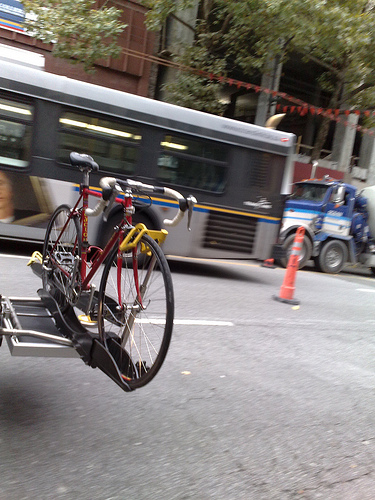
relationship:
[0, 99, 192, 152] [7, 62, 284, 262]
yellow light inside of bus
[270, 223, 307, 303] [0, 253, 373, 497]
cone on pavement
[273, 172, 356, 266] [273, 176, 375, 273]
cab on cab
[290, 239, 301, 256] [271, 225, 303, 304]
white part of cone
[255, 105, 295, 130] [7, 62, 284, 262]
exhaust of bus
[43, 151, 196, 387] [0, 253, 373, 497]
bicycle above pavement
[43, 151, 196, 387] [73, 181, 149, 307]
bicycle has frame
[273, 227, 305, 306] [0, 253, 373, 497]
cone on pavement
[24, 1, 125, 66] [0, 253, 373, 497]
tree on pavement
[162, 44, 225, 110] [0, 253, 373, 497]
tree on pavement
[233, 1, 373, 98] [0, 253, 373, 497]
tree on pavement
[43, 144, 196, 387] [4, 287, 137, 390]
bicycle on bike rack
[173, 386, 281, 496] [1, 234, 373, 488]
cracks on road